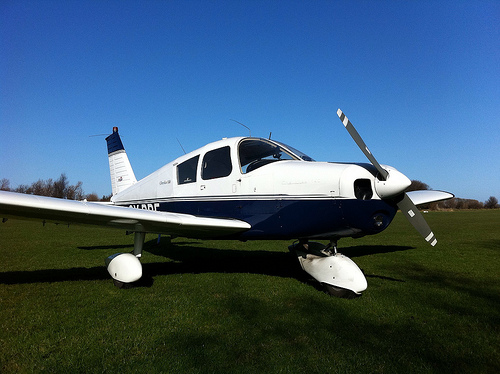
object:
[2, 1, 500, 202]
sky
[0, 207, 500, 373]
grass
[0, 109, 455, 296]
airplane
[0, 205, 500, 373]
ground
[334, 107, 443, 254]
propeller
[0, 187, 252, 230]
wing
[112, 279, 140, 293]
wheel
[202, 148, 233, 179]
window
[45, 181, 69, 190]
leaves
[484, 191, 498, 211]
tree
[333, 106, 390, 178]
propeller blade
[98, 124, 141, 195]
tail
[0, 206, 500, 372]
field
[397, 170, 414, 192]
nose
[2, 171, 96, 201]
trees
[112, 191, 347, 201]
stripes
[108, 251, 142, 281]
covers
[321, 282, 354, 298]
wheels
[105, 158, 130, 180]
rear tail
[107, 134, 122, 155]
rear tail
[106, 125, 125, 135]
tail light